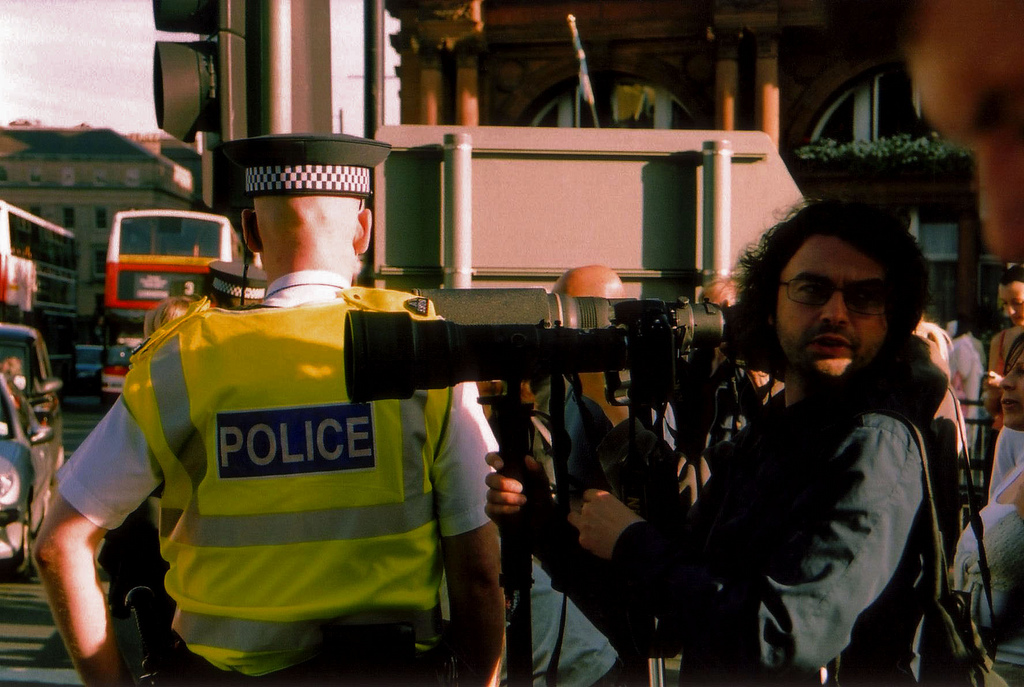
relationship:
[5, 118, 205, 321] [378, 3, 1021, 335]
building on building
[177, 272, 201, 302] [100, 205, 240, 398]
number 3 on front of bus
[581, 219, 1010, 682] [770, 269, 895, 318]
man wearing eye glasses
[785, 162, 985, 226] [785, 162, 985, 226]
pot in pot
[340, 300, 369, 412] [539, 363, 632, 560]
lens on camera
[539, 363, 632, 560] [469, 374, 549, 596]
camera on monopod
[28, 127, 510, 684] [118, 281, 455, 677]
man wearing vest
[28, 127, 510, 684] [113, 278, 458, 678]
man wearing police vest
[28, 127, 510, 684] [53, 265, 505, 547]
man wearing white shirt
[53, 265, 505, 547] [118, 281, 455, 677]
white shirt under vest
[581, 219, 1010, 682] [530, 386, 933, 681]
man wearing dark shirt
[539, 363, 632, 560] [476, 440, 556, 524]
camera in hand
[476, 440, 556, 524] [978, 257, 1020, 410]
hand on person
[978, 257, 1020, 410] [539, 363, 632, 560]
person holding camera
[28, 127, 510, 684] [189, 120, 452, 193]
man wearing a hat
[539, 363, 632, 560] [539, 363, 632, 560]
camera on pole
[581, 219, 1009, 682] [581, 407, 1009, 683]
man wearing a top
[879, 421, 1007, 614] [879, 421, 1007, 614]
bag on shoulder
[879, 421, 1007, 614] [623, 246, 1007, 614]
shoulder of man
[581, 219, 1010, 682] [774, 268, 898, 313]
man wearing spectacles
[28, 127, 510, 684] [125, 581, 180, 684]
man carrying baton's handle